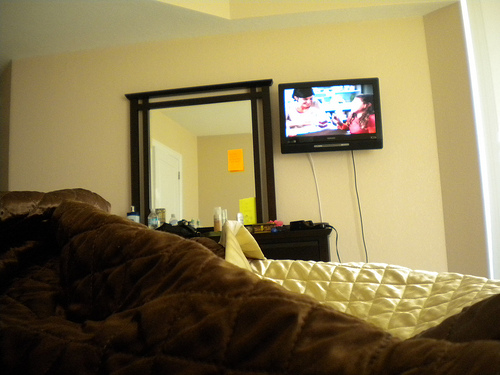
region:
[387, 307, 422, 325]
white square of blanket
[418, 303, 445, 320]
white square of blanket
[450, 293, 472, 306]
white square of blanket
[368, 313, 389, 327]
white square of blanket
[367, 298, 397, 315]
white square of blanket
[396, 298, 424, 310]
white square of blanket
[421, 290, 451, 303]
white square of blanket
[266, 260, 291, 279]
white square of blanket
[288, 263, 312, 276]
white square of blanket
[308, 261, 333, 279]
white square of blanket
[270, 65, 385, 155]
TV on the wall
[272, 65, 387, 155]
TV is color black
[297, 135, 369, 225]
two wires hanging from TV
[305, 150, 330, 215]
a white wire on wall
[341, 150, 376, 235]
a black wire on wall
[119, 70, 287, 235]
mirror near the TV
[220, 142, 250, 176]
an orange stick note on mirror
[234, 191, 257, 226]
a green stick note on mirror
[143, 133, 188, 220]
a white door reflected on mirror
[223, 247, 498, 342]
a white comforter on bed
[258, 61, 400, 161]
this is a television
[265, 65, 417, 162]
the television is turned on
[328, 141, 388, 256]
black chord on the wall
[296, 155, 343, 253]
white cord on the wall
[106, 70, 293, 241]
this is a mirror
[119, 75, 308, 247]
black trim around mirror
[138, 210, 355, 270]
this is a dresser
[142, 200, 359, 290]
the dresser is black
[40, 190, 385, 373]
this is a bedspread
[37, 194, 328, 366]
the bedspread is brown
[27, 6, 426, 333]
a messy room in a home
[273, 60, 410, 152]
a TV on the wall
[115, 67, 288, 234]
a mirror on the wall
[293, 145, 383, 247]
cords on the television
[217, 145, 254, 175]
an orange note on the mirror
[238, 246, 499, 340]
a white blanket on the bed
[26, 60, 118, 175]
a tan wall in the room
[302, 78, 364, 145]
There is a television that is on the wall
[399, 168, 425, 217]
There is dark cream wall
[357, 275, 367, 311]
There is a cream-colored blanket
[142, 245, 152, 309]
There is a brown blanket that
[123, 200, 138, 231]
There is a container of Vaseline lotion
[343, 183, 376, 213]
There is a black cord here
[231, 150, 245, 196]
There is an orange page here